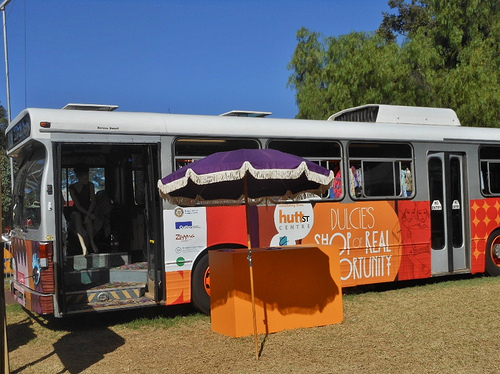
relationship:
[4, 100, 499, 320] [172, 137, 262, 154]
bus has window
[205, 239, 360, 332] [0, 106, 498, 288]
booth beside bus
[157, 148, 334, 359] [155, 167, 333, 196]
purple umbrella with trim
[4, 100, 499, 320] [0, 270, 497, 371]
bus parked grass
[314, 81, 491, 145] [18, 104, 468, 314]
unit on top of bus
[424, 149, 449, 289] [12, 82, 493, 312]
door of bus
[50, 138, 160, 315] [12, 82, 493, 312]
door of bus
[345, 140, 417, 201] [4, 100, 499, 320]
window on bus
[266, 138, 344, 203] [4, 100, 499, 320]
window on bus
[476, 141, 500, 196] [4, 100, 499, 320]
window on bus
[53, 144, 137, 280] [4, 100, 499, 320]
person inside bus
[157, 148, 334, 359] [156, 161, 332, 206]
purple umbrella with fringe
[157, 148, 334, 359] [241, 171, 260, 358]
purple umbrella with pole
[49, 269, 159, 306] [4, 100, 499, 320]
step going into bus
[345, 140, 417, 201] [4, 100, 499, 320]
window of bus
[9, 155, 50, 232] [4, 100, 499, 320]
window of bus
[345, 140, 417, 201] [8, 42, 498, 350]
window of bus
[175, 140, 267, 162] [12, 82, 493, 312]
window of bus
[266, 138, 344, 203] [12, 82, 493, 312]
window of bus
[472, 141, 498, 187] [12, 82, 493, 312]
window of bus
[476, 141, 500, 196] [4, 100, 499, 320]
window of bus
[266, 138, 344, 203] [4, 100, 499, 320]
window of bus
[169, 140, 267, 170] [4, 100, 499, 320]
window of bus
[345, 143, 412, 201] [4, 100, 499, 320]
window of bus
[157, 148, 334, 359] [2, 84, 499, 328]
purple umbrella next to bus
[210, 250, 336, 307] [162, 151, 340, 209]
shadow of umbrella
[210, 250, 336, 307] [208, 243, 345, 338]
shadow on booth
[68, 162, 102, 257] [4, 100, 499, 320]
person seated in front of bus